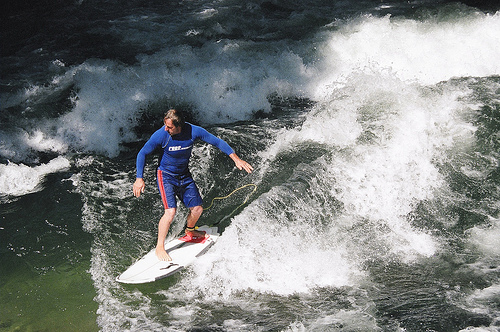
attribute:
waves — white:
[297, 60, 468, 322]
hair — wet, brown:
[165, 107, 177, 119]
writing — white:
[166, 142, 183, 153]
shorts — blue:
[129, 169, 230, 226]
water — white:
[203, 11, 488, 326]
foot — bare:
[149, 252, 187, 281]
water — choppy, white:
[4, 6, 487, 327]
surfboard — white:
[114, 223, 221, 284]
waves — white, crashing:
[214, 208, 369, 305]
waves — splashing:
[257, 161, 491, 325]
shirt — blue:
[129, 122, 227, 222]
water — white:
[55, 257, 358, 332]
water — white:
[8, 194, 462, 332]